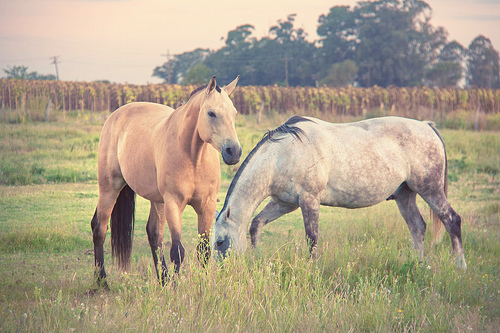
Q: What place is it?
A: It is a meadow.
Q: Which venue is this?
A: This is a meadow.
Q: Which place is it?
A: It is a meadow.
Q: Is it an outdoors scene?
A: Yes, it is outdoors.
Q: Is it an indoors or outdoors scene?
A: It is outdoors.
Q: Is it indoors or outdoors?
A: It is outdoors.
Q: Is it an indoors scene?
A: No, it is outdoors.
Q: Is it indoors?
A: No, it is outdoors.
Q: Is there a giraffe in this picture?
A: No, there are no giraffes.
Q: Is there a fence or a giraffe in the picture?
A: No, there are no giraffes or fences.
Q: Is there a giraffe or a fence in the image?
A: No, there are no giraffes or fences.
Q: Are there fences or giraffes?
A: No, there are no giraffes or fences.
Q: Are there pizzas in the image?
A: No, there are no pizzas.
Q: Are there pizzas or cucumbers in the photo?
A: No, there are no pizzas or cucumbers.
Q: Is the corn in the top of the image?
A: Yes, the corn is in the top of the image.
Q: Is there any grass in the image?
A: Yes, there is grass.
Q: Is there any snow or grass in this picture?
A: Yes, there is grass.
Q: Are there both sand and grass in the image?
A: No, there is grass but no sand.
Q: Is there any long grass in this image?
A: Yes, there is long grass.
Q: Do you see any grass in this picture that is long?
A: Yes, there is grass that is long.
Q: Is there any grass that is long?
A: Yes, there is grass that is long.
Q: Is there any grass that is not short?
A: Yes, there is long grass.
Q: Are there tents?
A: No, there are no tents.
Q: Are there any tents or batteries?
A: No, there are no tents or batteries.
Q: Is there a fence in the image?
A: No, there are no fences.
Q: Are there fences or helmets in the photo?
A: No, there are no fences or helmets.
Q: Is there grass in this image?
A: Yes, there is grass.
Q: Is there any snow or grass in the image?
A: Yes, there is grass.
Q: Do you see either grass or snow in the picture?
A: Yes, there is grass.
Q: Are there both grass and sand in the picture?
A: No, there is grass but no sand.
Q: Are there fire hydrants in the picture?
A: No, there are no fire hydrants.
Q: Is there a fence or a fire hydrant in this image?
A: No, there are no fire hydrants or fences.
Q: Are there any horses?
A: Yes, there is a horse.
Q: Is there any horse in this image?
A: Yes, there is a horse.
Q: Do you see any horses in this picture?
A: Yes, there is a horse.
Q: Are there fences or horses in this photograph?
A: Yes, there is a horse.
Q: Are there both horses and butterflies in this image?
A: No, there is a horse but no butterflies.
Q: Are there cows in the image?
A: No, there are no cows.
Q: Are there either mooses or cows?
A: No, there are no cows or mooses.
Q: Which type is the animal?
A: The animal is a horse.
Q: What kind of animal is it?
A: The animal is a horse.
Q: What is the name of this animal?
A: This is a horse.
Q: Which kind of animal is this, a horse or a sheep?
A: This is a horse.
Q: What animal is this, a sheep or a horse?
A: This is a horse.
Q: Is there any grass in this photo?
A: Yes, there is grass.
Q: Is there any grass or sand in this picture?
A: Yes, there is grass.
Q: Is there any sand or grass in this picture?
A: Yes, there is grass.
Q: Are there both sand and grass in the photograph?
A: No, there is grass but no sand.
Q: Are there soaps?
A: No, there are no soaps.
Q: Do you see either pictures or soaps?
A: No, there are no soaps or pictures.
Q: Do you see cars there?
A: No, there are no cars.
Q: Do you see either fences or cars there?
A: No, there are no cars or fences.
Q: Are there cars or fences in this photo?
A: No, there are no cars or fences.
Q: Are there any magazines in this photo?
A: No, there are no magazines.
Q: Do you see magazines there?
A: No, there are no magazines.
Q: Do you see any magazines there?
A: No, there are no magazines.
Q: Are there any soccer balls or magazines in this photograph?
A: No, there are no magazines or soccer balls.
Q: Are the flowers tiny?
A: Yes, the flowers are tiny.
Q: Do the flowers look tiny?
A: Yes, the flowers are tiny.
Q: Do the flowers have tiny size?
A: Yes, the flowers are tiny.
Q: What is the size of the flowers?
A: The flowers are tiny.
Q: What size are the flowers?
A: The flowers are tiny.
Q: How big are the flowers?
A: The flowers are tiny.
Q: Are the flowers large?
A: No, the flowers are tiny.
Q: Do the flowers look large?
A: No, the flowers are tiny.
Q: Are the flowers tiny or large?
A: The flowers are tiny.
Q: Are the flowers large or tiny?
A: The flowers are tiny.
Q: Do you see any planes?
A: No, there are no planes.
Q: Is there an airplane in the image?
A: No, there are no airplanes.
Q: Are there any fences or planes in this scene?
A: No, there are no planes or fences.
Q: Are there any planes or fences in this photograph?
A: No, there are no planes or fences.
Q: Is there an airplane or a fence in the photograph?
A: No, there are no airplanes or fences.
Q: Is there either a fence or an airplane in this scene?
A: No, there are no airplanes or fences.